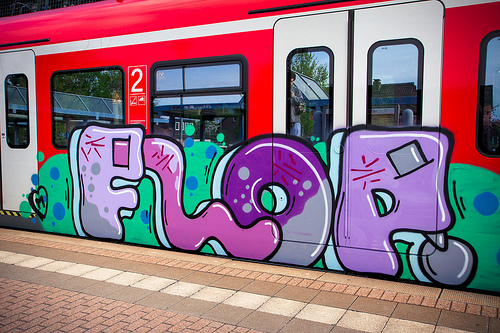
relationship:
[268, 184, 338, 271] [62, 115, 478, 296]
lettering on graffiti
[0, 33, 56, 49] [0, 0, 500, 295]
lines on train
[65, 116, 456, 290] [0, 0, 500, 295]
word painted on train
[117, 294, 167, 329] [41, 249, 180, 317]
bricks on sidewalk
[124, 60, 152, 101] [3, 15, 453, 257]
2 on train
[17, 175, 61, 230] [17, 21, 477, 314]
heart on train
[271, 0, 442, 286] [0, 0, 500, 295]
door on train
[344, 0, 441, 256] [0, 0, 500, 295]
door on train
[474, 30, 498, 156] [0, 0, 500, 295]
window on train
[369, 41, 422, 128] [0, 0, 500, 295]
window on train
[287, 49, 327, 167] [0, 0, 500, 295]
window on train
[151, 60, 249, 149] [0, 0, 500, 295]
window on train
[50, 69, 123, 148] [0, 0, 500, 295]
window on train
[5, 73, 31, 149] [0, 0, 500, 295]
window on train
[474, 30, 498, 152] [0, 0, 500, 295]
window on train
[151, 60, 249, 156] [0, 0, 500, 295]
window on train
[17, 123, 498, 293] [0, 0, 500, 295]
graffiti on train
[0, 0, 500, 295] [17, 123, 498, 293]
train on graffiti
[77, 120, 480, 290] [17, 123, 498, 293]
lettering on graffiti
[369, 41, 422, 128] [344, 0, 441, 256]
window on door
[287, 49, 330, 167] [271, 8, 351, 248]
window on train door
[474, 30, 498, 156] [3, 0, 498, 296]
window on train car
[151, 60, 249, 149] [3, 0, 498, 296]
window on train car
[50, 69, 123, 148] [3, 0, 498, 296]
window on train car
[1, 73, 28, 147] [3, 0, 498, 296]
window on train car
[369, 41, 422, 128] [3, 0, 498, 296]
window on train car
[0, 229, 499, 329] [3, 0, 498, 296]
platform next to train car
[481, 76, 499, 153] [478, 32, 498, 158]
reflection on window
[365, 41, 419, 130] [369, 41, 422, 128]
reflection on window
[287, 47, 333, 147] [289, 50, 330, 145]
reflection on window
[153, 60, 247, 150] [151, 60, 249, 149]
reflection on window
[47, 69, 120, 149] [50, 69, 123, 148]
reflection on window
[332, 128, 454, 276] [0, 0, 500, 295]
graffiti on train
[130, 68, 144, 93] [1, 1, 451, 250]
2 between white doors